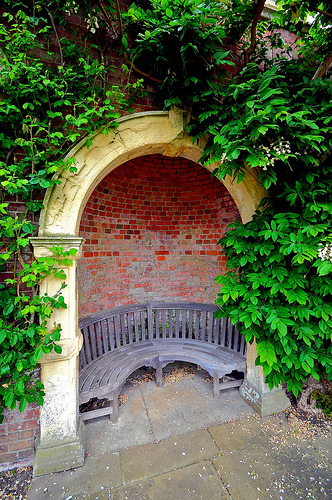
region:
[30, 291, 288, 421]
a bench shaped like a semi circle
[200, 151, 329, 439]
the leaves are green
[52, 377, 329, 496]
flower petals on the walkway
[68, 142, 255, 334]
a brick shelter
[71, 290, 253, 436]
the bench is gray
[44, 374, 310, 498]
the walkway is brown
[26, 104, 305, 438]
the entrance is yellow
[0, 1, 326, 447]
leaves surround the entrance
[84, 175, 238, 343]
the bricks are red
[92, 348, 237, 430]
leaves are under the bench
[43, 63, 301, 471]
old breaking archway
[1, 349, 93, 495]
discoloration at bottom of arch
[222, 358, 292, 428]
discoloration at bottom of arch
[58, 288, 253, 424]
wooden bench inside arch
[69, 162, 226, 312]
brick inside of arch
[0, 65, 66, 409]
green leaves at archway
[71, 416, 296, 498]
stone floor leading up to arch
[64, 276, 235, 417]
circular bench at arch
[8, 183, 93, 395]
white pillar of archway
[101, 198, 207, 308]
discolored stones at arch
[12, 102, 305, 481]
An alcove is pictured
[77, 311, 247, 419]
This is a bench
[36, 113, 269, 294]
An archway is here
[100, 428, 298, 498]
This area is paved with stone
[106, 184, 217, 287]
These are bricks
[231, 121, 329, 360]
Plants are growing here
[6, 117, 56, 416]
Vines are growing up the wall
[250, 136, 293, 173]
Flowers are blooming on the plant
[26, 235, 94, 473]
This is made of stone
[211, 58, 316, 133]
The leaves are green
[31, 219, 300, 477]
a unique sitting area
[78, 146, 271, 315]
a red brick wall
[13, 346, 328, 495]
an unkept seating area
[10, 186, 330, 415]
greenery around the bench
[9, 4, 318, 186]
green leaves over the seating area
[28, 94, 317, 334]
yellow arch over the seat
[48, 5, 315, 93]
brick wall behind the trees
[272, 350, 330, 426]
a root growing from the trees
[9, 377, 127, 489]
this part of the arch needs some paint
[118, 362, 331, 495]
this part of the area needs to be swept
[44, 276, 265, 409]
The bench is curved.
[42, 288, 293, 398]
The bench is metal.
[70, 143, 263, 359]
The wall is brick.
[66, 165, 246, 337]
The wall is red.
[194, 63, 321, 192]
The vines are green.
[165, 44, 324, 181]
The vines are leafy.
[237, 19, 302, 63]
Some leaves are orange.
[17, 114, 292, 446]
The archway is tan.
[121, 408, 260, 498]
The concrete slabs are on the ground.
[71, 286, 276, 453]
The bench is grey.